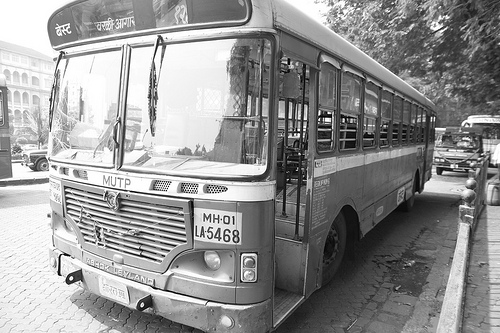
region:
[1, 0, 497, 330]
the picture is black and white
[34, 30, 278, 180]
the bus has a windshield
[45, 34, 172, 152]
the bus has windshield wipers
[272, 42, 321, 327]
the buses door is opened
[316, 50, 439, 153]
the bus has many windows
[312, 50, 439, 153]
the buses windows are open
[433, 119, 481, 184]
the van is behind the bus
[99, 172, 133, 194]
the front of the bus has the letters mutp on it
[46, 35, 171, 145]
the wipers are pointed down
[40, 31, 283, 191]
the windshield is large and reflective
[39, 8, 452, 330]
A bus next to the side walk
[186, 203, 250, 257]
White and black sign on bus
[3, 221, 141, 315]
The road is cobble stone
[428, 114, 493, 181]
Vehicle behind the bus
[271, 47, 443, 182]
The bus windows have bars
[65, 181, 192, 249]
Thin string on the bus radiator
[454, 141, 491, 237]
Fence between the road and side walk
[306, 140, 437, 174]
White stripe on side of bus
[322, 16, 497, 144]
Tree branches over the road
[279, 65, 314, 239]
Black poles inside the bus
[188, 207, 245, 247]
a sign "MH-01 LA-5468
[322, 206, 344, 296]
a tire on a bus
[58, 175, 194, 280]
a grate on a bus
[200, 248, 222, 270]
a light on a bus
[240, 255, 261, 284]
a turn signal on a bus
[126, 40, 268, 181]
a windshield on a bus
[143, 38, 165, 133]
a windshield wiper on a bus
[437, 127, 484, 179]
a van on a street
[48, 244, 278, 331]
a bumper on a bus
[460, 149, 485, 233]
a wooden post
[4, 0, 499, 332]
the picture is in black and white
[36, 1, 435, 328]
the bus is parked on the street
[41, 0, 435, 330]
the bus is empty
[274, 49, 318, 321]
the bus door is open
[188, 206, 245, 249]
a sign is on the bus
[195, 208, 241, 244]
the lettering is black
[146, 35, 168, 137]
a windshield wiper is on the bus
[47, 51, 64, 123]
a windshield wiper is on the bus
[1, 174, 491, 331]
the pavement is made of brick rock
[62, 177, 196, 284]
the grill is in front of the bus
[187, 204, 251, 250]
the bus has an ID number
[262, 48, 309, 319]
the door to the bus is open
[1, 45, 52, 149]
a building with windows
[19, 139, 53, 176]
the front end of a vehicle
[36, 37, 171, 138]
the windshield wipers of the bus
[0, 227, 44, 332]
the roadway is paved with brick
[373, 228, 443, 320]
part of the brick road is breaking up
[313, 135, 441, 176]
the bus has a white stripe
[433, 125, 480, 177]
a vehicle behind the bus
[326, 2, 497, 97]
trees hanging over the road